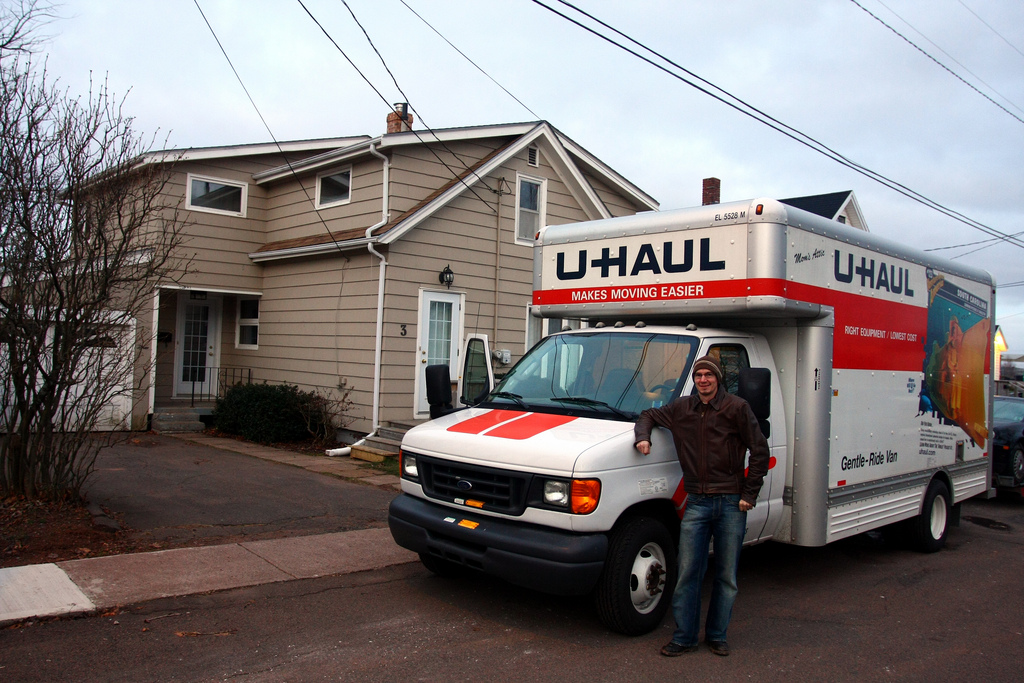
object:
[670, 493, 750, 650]
jeans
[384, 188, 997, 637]
uhaul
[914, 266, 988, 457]
picture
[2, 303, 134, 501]
garage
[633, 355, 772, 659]
person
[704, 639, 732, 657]
shoe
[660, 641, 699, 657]
shoe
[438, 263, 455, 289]
light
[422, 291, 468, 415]
door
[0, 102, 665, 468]
house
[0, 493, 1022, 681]
road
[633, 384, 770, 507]
leather jacket